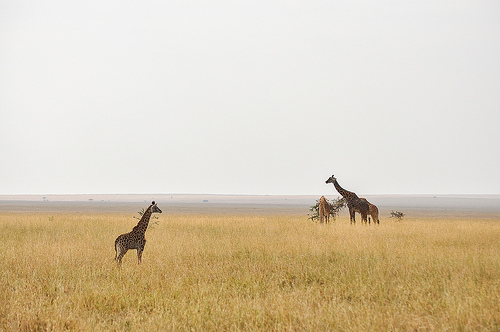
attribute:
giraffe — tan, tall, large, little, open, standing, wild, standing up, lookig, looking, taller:
[322, 172, 371, 224]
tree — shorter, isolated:
[310, 191, 345, 224]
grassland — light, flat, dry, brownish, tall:
[1, 195, 499, 331]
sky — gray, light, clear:
[0, 0, 499, 196]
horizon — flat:
[0, 191, 499, 211]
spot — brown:
[340, 189, 344, 194]